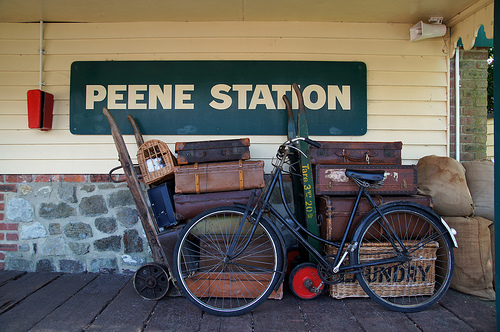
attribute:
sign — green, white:
[53, 29, 380, 160]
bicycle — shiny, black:
[170, 134, 457, 316]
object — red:
[24, 87, 59, 131]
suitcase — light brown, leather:
[174, 137, 268, 196]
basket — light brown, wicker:
[319, 235, 449, 295]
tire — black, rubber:
[172, 205, 282, 316]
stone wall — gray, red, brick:
[1, 169, 153, 270]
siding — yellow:
[379, 2, 439, 141]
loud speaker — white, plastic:
[403, 18, 448, 40]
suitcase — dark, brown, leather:
[168, 137, 252, 162]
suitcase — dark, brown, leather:
[177, 189, 265, 215]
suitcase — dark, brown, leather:
[310, 141, 402, 164]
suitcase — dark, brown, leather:
[314, 165, 419, 195]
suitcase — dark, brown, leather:
[323, 197, 429, 242]